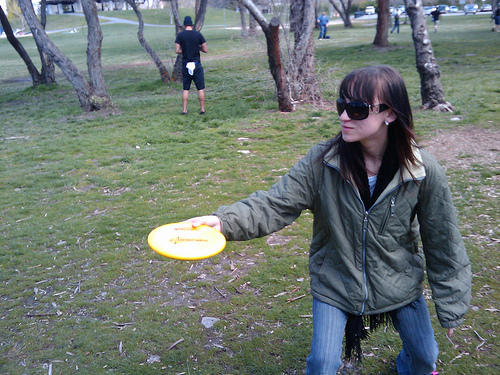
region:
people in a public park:
[11, 5, 482, 362]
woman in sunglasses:
[325, 55, 415, 160]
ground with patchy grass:
[7, 285, 247, 362]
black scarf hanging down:
[340, 295, 390, 355]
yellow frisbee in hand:
[140, 195, 245, 270]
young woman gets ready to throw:
[145, 65, 480, 365]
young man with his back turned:
[165, 10, 215, 115]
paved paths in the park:
[98, 10, 134, 28]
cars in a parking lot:
[440, 0, 490, 11]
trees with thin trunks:
[3, 3, 173, 113]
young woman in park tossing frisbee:
[147, 35, 498, 372]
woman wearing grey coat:
[310, 62, 465, 372]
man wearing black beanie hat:
[163, 13, 222, 119]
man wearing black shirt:
[161, 0, 233, 117]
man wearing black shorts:
[158, 7, 221, 117]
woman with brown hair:
[143, 62, 483, 374]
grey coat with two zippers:
[160, 113, 495, 341]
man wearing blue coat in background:
[314, 0, 338, 55]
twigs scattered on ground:
[5, 180, 317, 362]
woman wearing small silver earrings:
[299, 60, 425, 186]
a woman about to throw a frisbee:
[124, 60, 483, 370]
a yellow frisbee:
[145, 200, 228, 265]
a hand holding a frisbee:
[142, 215, 232, 270]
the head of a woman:
[328, 66, 413, 149]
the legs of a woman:
[296, 278, 441, 374]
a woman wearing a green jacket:
[221, 68, 487, 326]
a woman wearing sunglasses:
[323, 58, 414, 152]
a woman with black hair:
[318, 64, 433, 196]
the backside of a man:
[166, 13, 217, 120]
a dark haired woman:
[157, 66, 475, 370]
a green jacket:
[217, 131, 482, 328]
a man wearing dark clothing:
[170, 16, 210, 118]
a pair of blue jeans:
[296, 298, 443, 374]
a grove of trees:
[1, 0, 496, 120]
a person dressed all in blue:
[315, 8, 334, 42]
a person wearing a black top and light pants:
[425, 6, 447, 29]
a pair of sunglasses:
[332, 96, 395, 121]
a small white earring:
[382, 116, 392, 124]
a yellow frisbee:
[144, 204, 247, 291]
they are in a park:
[120, 9, 471, 374]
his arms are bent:
[157, 8, 232, 115]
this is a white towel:
[184, 59, 197, 79]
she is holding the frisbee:
[134, 34, 494, 374]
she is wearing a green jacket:
[187, 52, 487, 329]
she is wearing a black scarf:
[345, 158, 406, 363]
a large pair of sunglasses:
[333, 95, 389, 121]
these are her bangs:
[333, 71, 387, 103]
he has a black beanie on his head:
[181, 12, 196, 32]